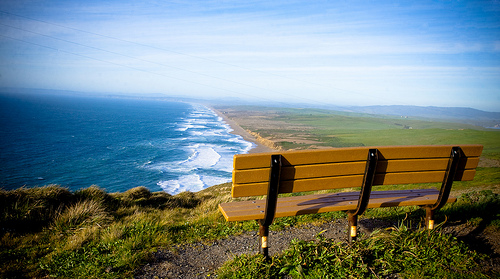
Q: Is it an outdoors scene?
A: Yes, it is outdoors.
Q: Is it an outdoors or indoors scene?
A: It is outdoors.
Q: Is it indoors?
A: No, it is outdoors.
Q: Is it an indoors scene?
A: No, it is outdoors.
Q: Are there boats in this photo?
A: No, there are no boats.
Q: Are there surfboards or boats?
A: No, there are no boats or surfboards.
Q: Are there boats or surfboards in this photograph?
A: No, there are no boats or surfboards.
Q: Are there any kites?
A: No, there are no kites.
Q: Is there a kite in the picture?
A: No, there are no kites.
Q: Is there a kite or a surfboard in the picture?
A: No, there are no kites or surfboards.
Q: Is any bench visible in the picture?
A: Yes, there is a bench.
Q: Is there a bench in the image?
A: Yes, there is a bench.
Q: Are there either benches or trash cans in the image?
A: Yes, there is a bench.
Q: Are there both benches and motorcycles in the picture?
A: No, there is a bench but no motorcycles.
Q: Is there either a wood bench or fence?
A: Yes, there is a wood bench.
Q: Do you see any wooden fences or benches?
A: Yes, there is a wood bench.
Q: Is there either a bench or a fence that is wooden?
A: Yes, the bench is wooden.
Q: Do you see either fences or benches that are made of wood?
A: Yes, the bench is made of wood.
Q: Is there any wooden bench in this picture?
A: Yes, there is a wood bench.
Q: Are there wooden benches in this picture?
A: Yes, there is a wood bench.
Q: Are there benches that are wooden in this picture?
A: Yes, there is a wood bench.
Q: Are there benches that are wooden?
A: Yes, there is a bench that is wooden.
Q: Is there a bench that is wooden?
A: Yes, there is a bench that is wooden.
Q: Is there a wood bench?
A: Yes, there is a bench that is made of wood.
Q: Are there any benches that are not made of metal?
A: Yes, there is a bench that is made of wood.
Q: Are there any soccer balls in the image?
A: No, there are no soccer balls.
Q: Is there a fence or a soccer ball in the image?
A: No, there are no soccer balls or fences.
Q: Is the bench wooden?
A: Yes, the bench is wooden.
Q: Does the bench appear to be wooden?
A: Yes, the bench is wooden.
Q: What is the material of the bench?
A: The bench is made of wood.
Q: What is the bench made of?
A: The bench is made of wood.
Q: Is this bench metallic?
A: No, the bench is wooden.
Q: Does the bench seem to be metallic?
A: No, the bench is wooden.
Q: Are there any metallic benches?
A: No, there is a bench but it is wooden.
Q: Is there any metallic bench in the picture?
A: No, there is a bench but it is wooden.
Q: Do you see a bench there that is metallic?
A: No, there is a bench but it is wooden.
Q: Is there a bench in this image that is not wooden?
A: No, there is a bench but it is wooden.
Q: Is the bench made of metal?
A: No, the bench is made of wood.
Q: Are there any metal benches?
A: No, there is a bench but it is made of wood.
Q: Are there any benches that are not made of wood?
A: No, there is a bench but it is made of wood.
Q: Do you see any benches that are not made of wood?
A: No, there is a bench but it is made of wood.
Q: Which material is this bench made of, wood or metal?
A: The bench is made of wood.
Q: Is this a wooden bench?
A: Yes, this is a wooden bench.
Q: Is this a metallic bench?
A: No, this is a wooden bench.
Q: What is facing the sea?
A: The bench is facing the sea.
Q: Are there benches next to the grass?
A: Yes, there is a bench next to the grass.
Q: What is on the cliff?
A: The bench is on the cliff.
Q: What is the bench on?
A: The bench is on the cliff.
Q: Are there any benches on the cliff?
A: Yes, there is a bench on the cliff.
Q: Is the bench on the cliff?
A: Yes, the bench is on the cliff.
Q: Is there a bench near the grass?
A: Yes, there is a bench near the grass.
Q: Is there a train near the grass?
A: No, there is a bench near the grass.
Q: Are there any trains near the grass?
A: No, there is a bench near the grass.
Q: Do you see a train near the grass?
A: No, there is a bench near the grass.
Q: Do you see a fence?
A: No, there are no fences.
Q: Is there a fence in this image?
A: No, there are no fences.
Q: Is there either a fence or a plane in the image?
A: No, there are no fences or airplanes.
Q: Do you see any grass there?
A: Yes, there is grass.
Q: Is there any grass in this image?
A: Yes, there is grass.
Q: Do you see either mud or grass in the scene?
A: Yes, there is grass.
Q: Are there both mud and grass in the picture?
A: No, there is grass but no mud.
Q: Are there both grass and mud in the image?
A: No, there is grass but no mud.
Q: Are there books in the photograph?
A: No, there are no books.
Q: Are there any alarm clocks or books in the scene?
A: No, there are no books or alarm clocks.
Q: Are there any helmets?
A: No, there are no helmets.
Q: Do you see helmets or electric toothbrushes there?
A: No, there are no helmets or electric toothbrushes.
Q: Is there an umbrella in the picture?
A: No, there are no umbrellas.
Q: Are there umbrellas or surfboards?
A: No, there are no umbrellas or surfboards.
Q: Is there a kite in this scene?
A: No, there are no kites.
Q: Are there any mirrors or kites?
A: No, there are no kites or mirrors.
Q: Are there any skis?
A: No, there are no skis.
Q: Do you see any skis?
A: No, there are no skis.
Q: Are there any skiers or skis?
A: No, there are no skis or skiers.